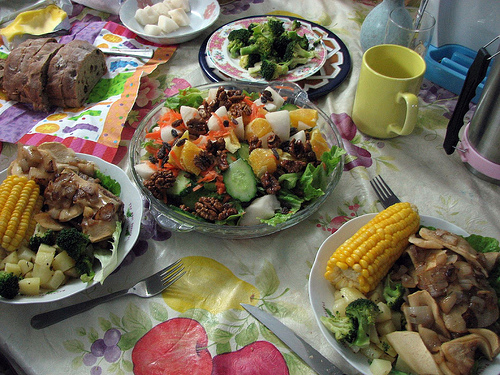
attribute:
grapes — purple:
[77, 323, 124, 373]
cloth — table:
[4, 4, 499, 374]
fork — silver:
[34, 254, 221, 341]